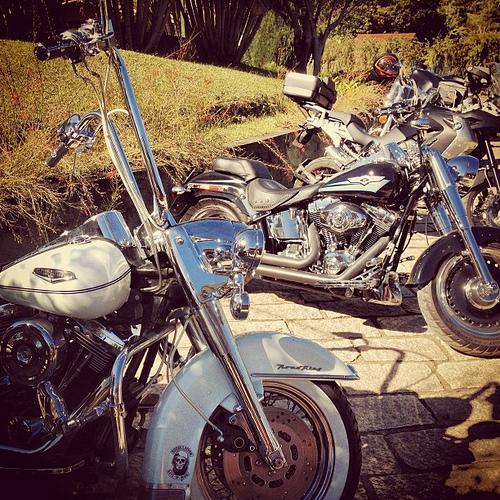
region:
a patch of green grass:
[5, 24, 370, 240]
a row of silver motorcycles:
[10, 30, 498, 485]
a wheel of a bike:
[129, 300, 389, 499]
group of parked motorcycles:
[12, 20, 497, 488]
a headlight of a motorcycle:
[183, 187, 329, 291]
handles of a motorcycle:
[13, 5, 120, 183]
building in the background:
[342, 17, 430, 59]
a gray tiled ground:
[1, 101, 488, 496]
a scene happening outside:
[6, 5, 477, 496]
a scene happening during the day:
[7, 5, 492, 487]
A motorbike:
[146, 374, 408, 466]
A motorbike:
[174, 333, 213, 377]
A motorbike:
[167, 268, 251, 450]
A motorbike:
[228, 334, 295, 448]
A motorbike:
[179, 334, 289, 479]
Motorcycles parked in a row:
[5, 20, 498, 488]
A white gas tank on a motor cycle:
[2, 221, 143, 328]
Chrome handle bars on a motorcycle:
[25, 15, 226, 309]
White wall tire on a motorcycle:
[146, 366, 385, 498]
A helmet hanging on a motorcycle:
[369, 48, 409, 83]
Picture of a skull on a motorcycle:
[159, 441, 202, 489]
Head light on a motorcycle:
[445, 145, 489, 199]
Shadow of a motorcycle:
[263, 299, 498, 486]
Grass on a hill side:
[4, 31, 359, 179]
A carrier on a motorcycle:
[274, 60, 358, 132]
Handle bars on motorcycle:
[24, 28, 135, 174]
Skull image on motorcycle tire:
[165, 445, 194, 484]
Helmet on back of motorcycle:
[369, 50, 403, 82]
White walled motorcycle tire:
[143, 352, 361, 497]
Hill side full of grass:
[5, 38, 280, 187]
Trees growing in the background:
[7, 2, 390, 73]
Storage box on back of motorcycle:
[277, 67, 341, 115]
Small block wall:
[5, 125, 311, 242]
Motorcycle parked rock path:
[177, 118, 497, 346]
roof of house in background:
[344, 27, 422, 52]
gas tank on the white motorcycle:
[5, 232, 133, 319]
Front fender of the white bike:
[149, 321, 285, 498]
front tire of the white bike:
[192, 369, 374, 499]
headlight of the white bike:
[189, 214, 259, 291]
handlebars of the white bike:
[36, 19, 199, 225]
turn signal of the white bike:
[230, 291, 257, 320]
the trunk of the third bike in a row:
[280, 68, 345, 113]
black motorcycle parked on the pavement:
[200, 139, 498, 279]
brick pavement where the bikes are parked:
[356, 334, 466, 466]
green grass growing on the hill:
[126, 52, 275, 112]